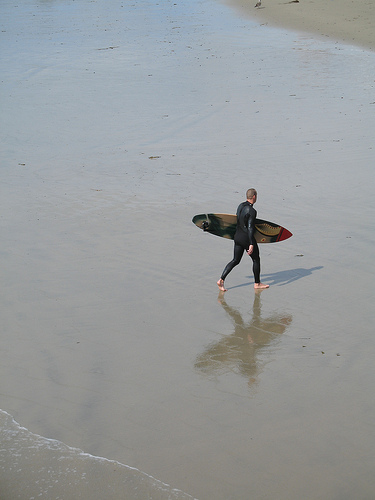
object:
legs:
[216, 235, 270, 292]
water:
[187, 135, 218, 174]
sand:
[311, 81, 366, 153]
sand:
[201, 389, 280, 452]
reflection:
[196, 282, 296, 393]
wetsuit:
[234, 201, 258, 245]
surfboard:
[191, 212, 293, 245]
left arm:
[235, 202, 244, 221]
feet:
[216, 277, 269, 292]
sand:
[10, 10, 66, 64]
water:
[85, 273, 138, 347]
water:
[320, 53, 363, 124]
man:
[216, 188, 270, 293]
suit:
[220, 200, 261, 284]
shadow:
[225, 264, 325, 291]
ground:
[311, 426, 375, 500]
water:
[0, 409, 51, 499]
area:
[6, 3, 109, 81]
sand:
[57, 336, 127, 430]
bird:
[253, 1, 262, 9]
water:
[216, 323, 300, 400]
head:
[246, 188, 258, 204]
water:
[96, 457, 149, 495]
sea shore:
[0, 0, 367, 496]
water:
[4, 3, 63, 163]